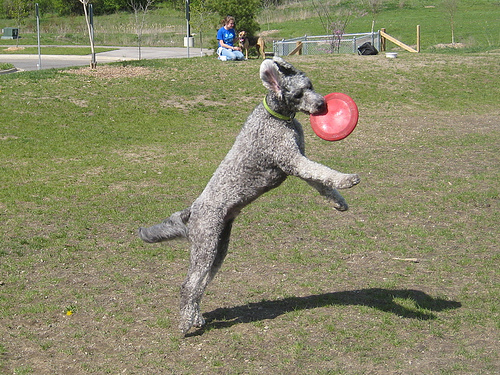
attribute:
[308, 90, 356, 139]
frisbee — red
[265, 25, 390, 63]
fence — metal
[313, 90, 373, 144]
frisbee — red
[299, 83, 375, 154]
frisbee — red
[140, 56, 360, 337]
dog — salt and pepper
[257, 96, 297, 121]
collar — yellow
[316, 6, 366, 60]
tree — small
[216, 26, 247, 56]
shirt — blue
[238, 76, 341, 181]
collar — green